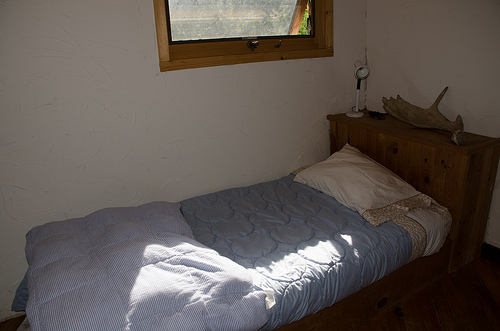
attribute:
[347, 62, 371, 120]
lamp — small, white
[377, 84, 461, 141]
antler — animal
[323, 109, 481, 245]
headboard — large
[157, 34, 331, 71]
frame — wooden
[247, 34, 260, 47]
device — window's, locking, part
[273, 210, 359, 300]
blanket — one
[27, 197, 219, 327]
blanket — one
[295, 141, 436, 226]
pillow case — matching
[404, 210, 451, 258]
sheet — matching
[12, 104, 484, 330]
bed — wooden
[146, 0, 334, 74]
window — opened, partially open, wooden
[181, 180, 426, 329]
bed-cover — blue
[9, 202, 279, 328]
duvet — blue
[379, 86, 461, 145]
branch — wooden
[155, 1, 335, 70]
window — frosted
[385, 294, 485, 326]
floor — hardwood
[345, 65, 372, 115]
lamp — white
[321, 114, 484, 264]
headboard — large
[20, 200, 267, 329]
blanket — blue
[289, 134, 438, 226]
pillow — white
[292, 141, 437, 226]
pillow — white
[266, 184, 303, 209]
circle — blue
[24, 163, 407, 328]
blanket — blue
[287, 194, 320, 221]
circle — blue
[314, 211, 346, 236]
circle — blue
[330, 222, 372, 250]
circle — blue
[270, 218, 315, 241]
circle — blue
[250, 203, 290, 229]
circle — blue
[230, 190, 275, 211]
circle — blue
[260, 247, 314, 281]
circle — blue